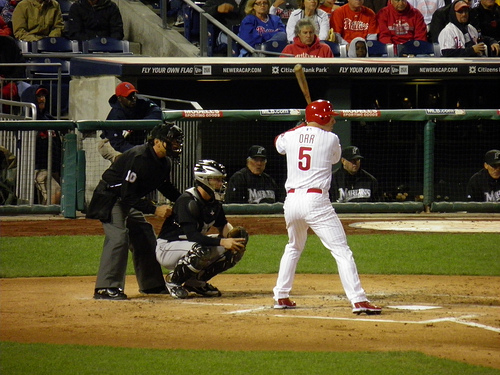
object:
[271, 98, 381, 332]
baseball player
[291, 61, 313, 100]
bat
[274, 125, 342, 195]
jersey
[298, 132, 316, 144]
name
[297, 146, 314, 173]
number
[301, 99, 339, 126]
helmet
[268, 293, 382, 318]
shoes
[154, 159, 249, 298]
catcher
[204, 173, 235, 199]
mask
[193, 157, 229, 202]
helmet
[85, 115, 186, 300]
umpire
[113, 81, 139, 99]
hat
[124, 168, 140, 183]
number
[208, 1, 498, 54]
fans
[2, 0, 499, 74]
bleachers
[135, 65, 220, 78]
words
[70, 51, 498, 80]
dugout roof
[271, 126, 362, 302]
uniform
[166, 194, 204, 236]
black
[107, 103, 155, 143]
sweatshirt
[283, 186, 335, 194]
belt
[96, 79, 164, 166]
man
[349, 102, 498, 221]
railing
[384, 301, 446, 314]
home plate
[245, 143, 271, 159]
baseball cap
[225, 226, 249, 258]
glove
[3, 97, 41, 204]
fence